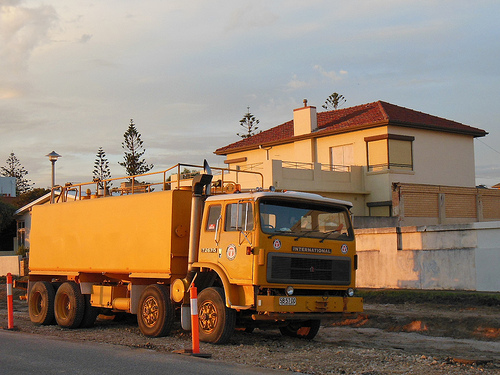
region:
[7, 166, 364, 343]
a bright yellow truck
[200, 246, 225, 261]
white writing on the truck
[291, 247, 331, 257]
white writing on the truck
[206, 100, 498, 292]
a house in the photo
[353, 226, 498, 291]
an off white fence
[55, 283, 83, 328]
a wheel of a truck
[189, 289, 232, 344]
a wheel of a truck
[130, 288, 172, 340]
a wheel of a truck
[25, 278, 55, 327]
a wheel of a truck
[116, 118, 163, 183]
a tree in the background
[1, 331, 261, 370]
paved road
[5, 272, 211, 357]
orange safety pilons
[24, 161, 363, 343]
large yellow truck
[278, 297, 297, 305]
white and black license plate on front of truck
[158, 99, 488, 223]
a house in the background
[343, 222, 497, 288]
a white cement wall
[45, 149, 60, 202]
a street light in the distance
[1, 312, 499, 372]
gravel at the edge of the road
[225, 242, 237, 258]
a logo on the door of the truck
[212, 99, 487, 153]
a tile roof on the house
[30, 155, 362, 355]
yellow truck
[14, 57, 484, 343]
truck next to house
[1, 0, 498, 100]
blue and grey sky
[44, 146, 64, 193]
streetlamp off in distance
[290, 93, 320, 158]
white and red chimney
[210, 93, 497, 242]
white and red house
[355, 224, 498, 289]
dirty cement fence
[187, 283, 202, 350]
orange and white construction reflecters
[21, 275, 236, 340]
four black tires with yellow rims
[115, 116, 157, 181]
green tree in distance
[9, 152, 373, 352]
yellow dump truck in the road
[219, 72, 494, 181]
building in the background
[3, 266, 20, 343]
orange safety poles in gravel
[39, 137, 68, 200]
light on a pole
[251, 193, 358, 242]
front window of a truck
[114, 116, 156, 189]
green tree behind truck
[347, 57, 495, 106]
blue cloudy sky in the distance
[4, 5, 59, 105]
white cloud in the sky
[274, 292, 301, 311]
license plate on truck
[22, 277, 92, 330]
back tires of a truck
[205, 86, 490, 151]
The roof is red.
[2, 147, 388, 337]
The truck is yellow.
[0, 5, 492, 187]
The sky is cloudy.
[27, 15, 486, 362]
Photo taken at sunset.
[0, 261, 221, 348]
Two orange safety markers.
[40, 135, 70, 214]
One light post behind the truck.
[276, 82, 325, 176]
Chimney on the house in the background.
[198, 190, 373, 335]
Nobody in cab of truck.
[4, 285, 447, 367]
Truck parked on gravel.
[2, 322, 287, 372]
Road next to truck.